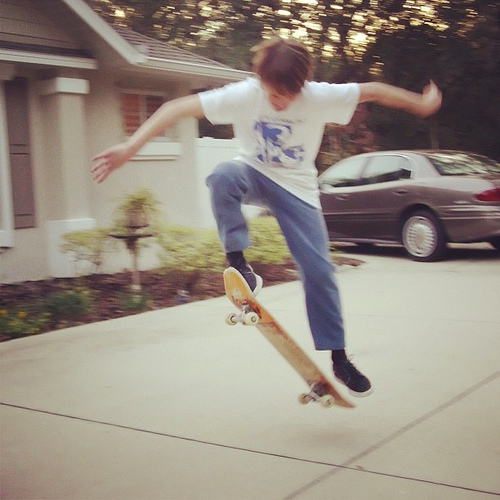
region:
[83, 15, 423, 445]
A boy on a skateboard.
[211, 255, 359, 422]
A skateboard with white wheels.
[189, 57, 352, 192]
A white short sleeve tee shirt.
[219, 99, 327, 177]
A graphic design on a tee shirt.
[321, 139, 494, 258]
A grey four door vehicle.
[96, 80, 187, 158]
A small window on a house.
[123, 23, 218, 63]
The roof on a house.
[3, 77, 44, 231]
A shutter on side of window.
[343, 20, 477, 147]
Trees in the background.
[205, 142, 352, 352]
A pair of blue pants.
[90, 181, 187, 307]
This is a pot.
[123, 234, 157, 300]
This is a brown pillar.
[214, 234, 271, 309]
This is a right shoe.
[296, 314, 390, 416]
This is a left shoe.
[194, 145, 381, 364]
These are blue pants.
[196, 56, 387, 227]
This is a white shirt.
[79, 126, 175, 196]
This is a left hand.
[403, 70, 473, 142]
This is a right hand.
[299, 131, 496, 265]
This is a car.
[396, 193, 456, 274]
This is a tire.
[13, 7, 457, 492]
the photo is blurry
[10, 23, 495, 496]
the photo was taken outside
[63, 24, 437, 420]
a person is in the photo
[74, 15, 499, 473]
the person is a boy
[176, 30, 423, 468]
the boy is wearing clothes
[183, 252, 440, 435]
the boy has a skateboard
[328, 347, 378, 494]
the boy has black shoes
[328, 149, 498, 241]
a vehicle is in the photo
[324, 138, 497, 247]
the vehicle is grey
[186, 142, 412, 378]
the boy has blue jeans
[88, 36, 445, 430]
young male skater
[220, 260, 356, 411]
orange skateboard with four white wheels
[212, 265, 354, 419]
orange skateboard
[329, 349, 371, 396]
black shoes on the skater's foot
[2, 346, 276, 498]
gray cement ground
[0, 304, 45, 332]
green plants growing from the dirt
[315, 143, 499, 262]
gray vehicle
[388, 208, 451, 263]
black wheel on gray vehicle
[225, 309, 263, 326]
front white wheels on the skateboard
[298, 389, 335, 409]
back white wheels on the skateboard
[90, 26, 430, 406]
The teenager is performing a trick.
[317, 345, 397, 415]
He has black shoes on.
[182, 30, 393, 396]
His pants are gray.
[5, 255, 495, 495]
The driveway.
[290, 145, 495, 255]
A car is parked in the driveway.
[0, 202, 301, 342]
Plants decorating the drive way.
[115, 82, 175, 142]
A small window.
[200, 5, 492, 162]
Trees are in the background.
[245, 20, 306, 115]
The teenager's hair is brown.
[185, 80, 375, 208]
The teenager is wearing a white shirt.